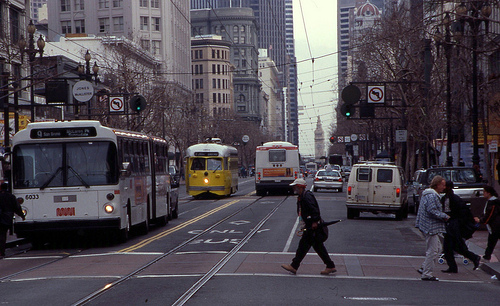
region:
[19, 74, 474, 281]
A busy city street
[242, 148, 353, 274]
A man walking across a street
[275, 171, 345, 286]
A man carrying an umbrella and wearing a tan hat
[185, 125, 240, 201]
A yellow streetcar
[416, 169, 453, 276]
A man in a denim shirt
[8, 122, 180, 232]
y busA white cit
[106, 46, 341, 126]
Power lines over a city street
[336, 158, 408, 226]
A white passenger van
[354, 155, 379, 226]
Ladder on the back of van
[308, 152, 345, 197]
A white taxi cab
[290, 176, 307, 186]
A white ball cap.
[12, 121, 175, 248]
A white bus.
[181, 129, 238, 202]
A yellow and white tram.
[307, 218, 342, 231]
A dark colored umbrella.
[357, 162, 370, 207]
A silver ladder.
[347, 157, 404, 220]
A cream colored van.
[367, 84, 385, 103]
A red, white, and black street sign.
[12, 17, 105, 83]
Street lights.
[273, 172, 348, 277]
A man walking across the street.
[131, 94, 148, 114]
A black traffic light displaying a green light.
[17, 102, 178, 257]
This is a bus.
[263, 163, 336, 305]
The man is crossing the street.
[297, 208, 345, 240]
The man has an umbrella.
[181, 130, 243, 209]
The trolley is yellow.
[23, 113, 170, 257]
The bus is white.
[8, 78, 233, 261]
These are used for public transportation.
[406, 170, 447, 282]
This man is wearing a jacket.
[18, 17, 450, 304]
This is a crosswalk.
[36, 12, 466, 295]
this is an urban setting.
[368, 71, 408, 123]
This is a "no left turn" sign.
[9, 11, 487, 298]
a busy city street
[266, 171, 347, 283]
a man walking across the street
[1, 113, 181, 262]
a white city bus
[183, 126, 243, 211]
a yellow and white street car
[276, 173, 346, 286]
a man carrying an umbrella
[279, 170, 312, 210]
a man wearing a white cap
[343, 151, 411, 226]
a white van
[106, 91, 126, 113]
a no left turn sign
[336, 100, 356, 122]
a traffic light on green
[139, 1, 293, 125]
several buildings in a city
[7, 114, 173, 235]
the white bus on the road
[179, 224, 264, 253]
the white words on the road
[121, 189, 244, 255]
the yellow lines on the street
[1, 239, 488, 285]
the crosswalk on the road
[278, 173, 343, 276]
the man in the crosswalk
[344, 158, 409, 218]
the white van on the road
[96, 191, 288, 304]
the track on the road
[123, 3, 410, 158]
the power lines above the road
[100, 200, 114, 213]
the light on the front of the white bus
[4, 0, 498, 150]
the buildings lining the street